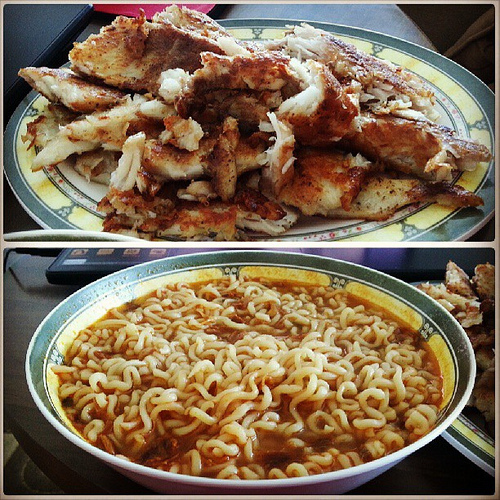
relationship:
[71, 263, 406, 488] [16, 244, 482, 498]
noodles in bowl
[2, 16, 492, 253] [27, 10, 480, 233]
plate beneath meat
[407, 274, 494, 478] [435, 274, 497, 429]
plate of meat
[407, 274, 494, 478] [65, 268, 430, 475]
plate next to noodles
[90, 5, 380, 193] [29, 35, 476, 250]
meat on plate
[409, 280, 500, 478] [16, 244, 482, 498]
plate next to bowl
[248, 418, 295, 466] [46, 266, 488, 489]
meat in soup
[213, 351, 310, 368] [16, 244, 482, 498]
noodles in bowl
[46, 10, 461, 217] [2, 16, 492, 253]
meat on plate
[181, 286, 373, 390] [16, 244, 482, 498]
noodles in bowl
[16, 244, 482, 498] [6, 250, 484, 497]
bowl sitting on table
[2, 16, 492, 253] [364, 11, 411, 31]
plate on table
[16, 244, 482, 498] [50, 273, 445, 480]
bowl of ramen noodles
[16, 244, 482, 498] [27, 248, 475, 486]
bowl with pattern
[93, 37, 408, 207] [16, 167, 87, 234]
fish on plate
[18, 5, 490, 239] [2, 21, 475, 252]
food on plate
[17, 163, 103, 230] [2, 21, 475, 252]
design on plate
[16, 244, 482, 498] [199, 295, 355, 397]
bowl of noodles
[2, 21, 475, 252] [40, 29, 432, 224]
plate full of fish